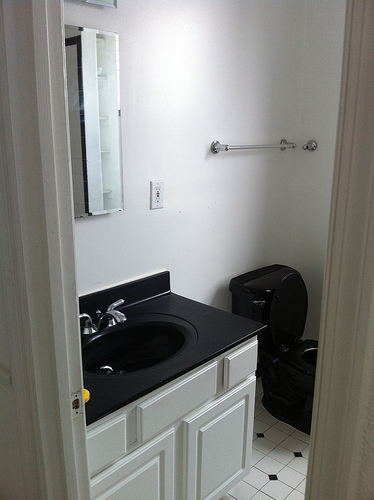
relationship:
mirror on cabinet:
[81, 30, 124, 212] [68, 23, 126, 220]